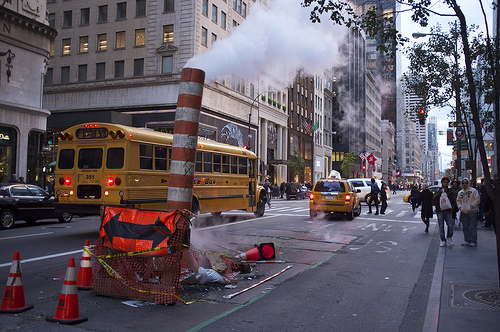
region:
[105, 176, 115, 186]
passenger side brake lights on a school bus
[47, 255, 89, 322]
an orange caution cone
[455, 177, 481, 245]
man in a white hoodie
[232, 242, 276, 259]
an orange safety cone on its side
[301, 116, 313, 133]
an American flag hanging from a building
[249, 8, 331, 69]
steam rising in a city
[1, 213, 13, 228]
the rear passenger side tire on a car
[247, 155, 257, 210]
the doors of a school bus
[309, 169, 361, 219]
a small yellow car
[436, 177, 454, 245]
a man with a shopping bag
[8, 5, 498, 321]
A city street scene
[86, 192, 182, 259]
An orange sign with arrows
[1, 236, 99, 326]
Orange caution cones with stripes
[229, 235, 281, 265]
An overturned caution cone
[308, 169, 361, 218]
A stopped orange taxi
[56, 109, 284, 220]
A stopped yellow school bus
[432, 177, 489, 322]
Pedestrians approaching the camera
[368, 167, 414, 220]
Pedestrians crossing the street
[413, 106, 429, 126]
A red traffic signal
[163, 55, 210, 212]
An orange and white tower spewing steam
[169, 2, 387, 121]
Steam emitting from an orange and white cylinder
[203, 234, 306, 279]
Knocked Over Traffic cones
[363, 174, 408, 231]
Pedesterians Crossing the intersection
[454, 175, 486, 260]
Pedesterian with a white hooded sweatshirt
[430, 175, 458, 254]
A Man carrying a shopping bag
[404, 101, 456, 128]
Traffic Light showing a Lit Red Stop Light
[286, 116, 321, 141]
US Flag Flying From a Building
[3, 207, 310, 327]
Traffic Cones Indicating a Road Hazard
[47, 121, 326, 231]
Yellow School Bus Stopped at the intersection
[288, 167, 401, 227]
Taxi waiting for intersection to clear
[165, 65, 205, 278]
the tall orange and white object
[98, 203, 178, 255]
the orange sign with the black arrow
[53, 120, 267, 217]
the yellow bus on the road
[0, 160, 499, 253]
the people in the city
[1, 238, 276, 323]
the orange cones on the ground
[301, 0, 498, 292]
the trees on the sidewalk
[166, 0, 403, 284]
the smoke coming from the orange and white object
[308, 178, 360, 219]
the yellow car on the road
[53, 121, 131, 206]
the lights on the back of the bus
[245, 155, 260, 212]
the doors to the bus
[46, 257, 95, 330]
an orange cone with white stripes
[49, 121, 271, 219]
a yellow school bus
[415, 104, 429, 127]
a red light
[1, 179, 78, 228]
a black car on the road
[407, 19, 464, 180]
a street light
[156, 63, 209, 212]
an orange and white smoke stack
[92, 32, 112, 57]
a lighted window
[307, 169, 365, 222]
a yellow taxi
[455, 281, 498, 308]
a man hole cover on the road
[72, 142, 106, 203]
the back door of a school bus